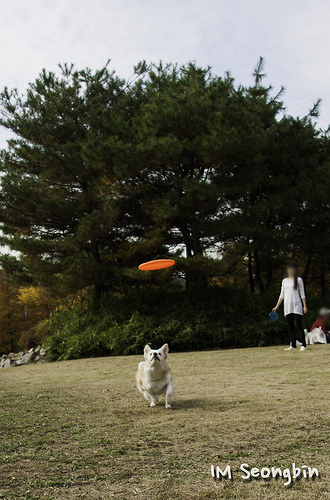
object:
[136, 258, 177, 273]
frisbee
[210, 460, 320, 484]
watermark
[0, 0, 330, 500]
picture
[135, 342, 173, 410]
dog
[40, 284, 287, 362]
bushes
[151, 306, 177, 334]
green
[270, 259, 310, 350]
woman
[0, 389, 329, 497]
grass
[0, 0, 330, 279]
sky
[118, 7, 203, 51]
blue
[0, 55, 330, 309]
tree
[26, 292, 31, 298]
leaf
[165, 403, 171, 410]
paw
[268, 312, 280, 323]
frisbee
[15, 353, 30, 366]
rocks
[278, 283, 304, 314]
white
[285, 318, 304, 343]
black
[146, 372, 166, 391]
beige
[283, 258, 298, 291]
hair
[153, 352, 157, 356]
nose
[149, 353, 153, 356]
eyes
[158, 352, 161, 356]
eye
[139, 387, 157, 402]
leg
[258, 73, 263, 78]
leaves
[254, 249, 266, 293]
trunk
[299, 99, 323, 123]
branches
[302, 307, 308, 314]
hand